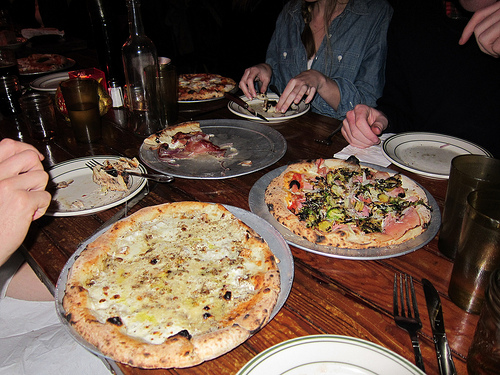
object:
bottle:
[117, 2, 165, 123]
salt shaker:
[105, 78, 126, 110]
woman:
[233, 2, 389, 121]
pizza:
[56, 201, 280, 370]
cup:
[56, 78, 106, 146]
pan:
[137, 115, 290, 183]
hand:
[278, 68, 325, 113]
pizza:
[266, 155, 431, 250]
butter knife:
[421, 276, 456, 373]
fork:
[85, 156, 175, 184]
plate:
[38, 152, 148, 217]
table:
[0, 35, 496, 370]